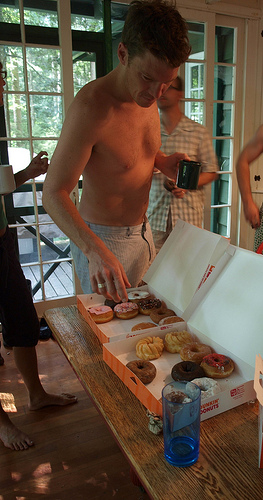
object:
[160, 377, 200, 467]
cup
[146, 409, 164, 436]
napkin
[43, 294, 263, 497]
table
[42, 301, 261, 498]
wood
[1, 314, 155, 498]
wood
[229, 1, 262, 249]
wood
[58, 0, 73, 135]
wood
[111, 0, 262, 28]
wood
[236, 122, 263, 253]
man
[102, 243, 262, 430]
doughnuts`s box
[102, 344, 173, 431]
front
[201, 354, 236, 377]
donuts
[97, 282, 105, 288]
ring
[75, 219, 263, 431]
two boxes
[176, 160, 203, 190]
glass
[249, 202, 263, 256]
shorts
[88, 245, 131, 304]
hand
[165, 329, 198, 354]
doughnut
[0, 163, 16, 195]
coffee cup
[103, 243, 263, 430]
carton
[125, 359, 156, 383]
donuts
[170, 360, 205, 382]
donuts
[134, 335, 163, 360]
donuts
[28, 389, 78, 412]
feet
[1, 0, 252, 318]
doors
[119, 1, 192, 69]
hair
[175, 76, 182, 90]
hair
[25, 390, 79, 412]
bare foot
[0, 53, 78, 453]
man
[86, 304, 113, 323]
donut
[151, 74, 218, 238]
man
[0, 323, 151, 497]
floor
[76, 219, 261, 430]
boxes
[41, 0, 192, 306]
man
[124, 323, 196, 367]
dustpan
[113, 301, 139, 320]
donut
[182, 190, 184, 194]
ring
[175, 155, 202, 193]
cup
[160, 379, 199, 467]
glass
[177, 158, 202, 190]
coffee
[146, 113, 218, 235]
shirt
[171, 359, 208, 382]
dunkin donut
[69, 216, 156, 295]
pants